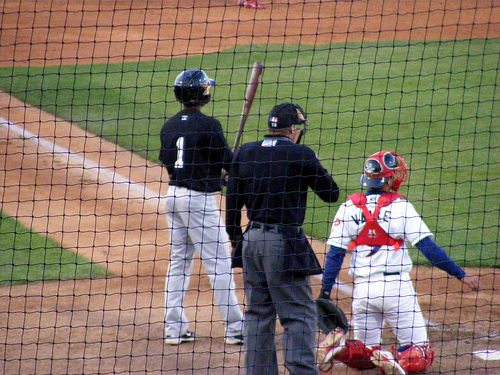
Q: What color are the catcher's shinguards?
A: Red.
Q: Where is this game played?
A: Baseball field.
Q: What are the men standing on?
A: Dirt.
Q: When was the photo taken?
A: During a game.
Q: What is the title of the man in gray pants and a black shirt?
A: Umpire.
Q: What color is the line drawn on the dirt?
A: White.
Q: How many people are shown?
A: Three.